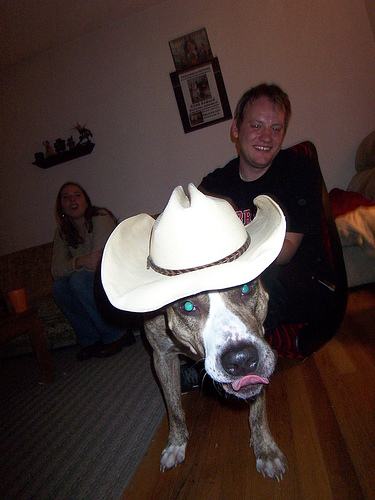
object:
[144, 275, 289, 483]
dog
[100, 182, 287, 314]
cowboy hat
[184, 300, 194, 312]
eye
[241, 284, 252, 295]
eye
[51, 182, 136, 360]
girl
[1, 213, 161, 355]
couch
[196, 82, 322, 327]
boy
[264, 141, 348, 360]
gaming chair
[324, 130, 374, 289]
recliner chair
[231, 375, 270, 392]
tongue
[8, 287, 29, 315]
cup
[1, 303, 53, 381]
coffee table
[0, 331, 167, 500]
rug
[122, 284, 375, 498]
floor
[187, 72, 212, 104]
picture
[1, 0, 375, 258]
wall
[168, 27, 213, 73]
picture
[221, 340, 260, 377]
nose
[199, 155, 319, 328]
shirt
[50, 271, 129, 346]
pants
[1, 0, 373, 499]
living room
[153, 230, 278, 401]
head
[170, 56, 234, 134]
newspaper article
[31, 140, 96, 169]
shelf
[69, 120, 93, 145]
knick knack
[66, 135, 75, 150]
knick knack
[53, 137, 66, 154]
knick knack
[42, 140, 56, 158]
knick knack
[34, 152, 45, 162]
knick knack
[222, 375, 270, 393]
mouth